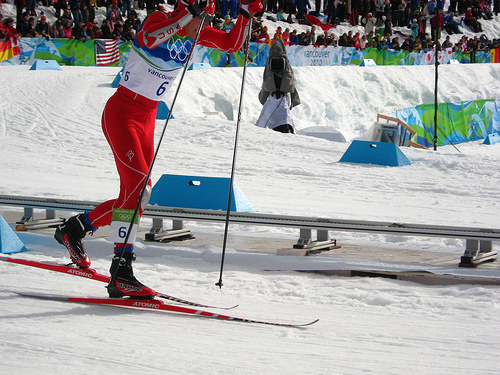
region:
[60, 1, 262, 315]
Olympic skier from the USA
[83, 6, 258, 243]
red, white and blue ski suit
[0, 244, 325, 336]
pair of skies with red edge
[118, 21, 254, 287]
two black ski poles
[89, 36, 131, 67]
flag of the USA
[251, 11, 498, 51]
a line of spectators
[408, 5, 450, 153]
a black pole off to the side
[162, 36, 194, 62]
the olympic games logo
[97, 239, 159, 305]
black and red ski boot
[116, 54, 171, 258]
athlete's entry number 6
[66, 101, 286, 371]
this person is dressed in red ski pants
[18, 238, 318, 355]
his skis are red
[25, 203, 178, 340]
his ski boots are red as well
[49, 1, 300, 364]
he is holding two poles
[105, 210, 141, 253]
his contestant number is 6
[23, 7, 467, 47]
many fans are in the stands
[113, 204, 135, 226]
the olympic symbol is on the patch on his leg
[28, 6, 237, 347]
he represents team USA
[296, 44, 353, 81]
this is in Vancouver several years ago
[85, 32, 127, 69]
the flag of the usa.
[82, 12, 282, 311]
Skier on skis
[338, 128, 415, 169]
Blue block in background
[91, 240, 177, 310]
Red and black ski boot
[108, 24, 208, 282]
Ski pole is long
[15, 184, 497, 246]
Railing just above snow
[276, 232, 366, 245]
One support of metal track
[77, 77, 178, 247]
Pants are red and bright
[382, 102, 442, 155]
Tube is yellow and twisty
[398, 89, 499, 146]
Green and blue tarp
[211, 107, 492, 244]
Snow is white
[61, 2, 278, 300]
Person is wearing a red sports suit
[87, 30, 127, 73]
An american flag in the background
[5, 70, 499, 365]
Snow is covering the ground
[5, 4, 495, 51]
A crowd of people in the background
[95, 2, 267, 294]
Person is holding ski poles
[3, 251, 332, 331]
The skis are red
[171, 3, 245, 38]
Person is wearing a helmet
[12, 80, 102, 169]
Ski tracks are in the snow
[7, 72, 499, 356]
The snow is white in color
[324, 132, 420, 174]
A small light blue snow ramp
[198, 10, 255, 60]
the arm of a man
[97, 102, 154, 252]
the leg of a man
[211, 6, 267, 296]
a metal ski pole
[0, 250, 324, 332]
a pair of red skis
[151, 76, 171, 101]
a number card on the man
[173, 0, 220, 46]
the head of a man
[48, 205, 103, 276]
a ski boot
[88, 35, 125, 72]
an American flag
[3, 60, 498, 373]
white snow on the ground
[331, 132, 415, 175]
a blue ramp